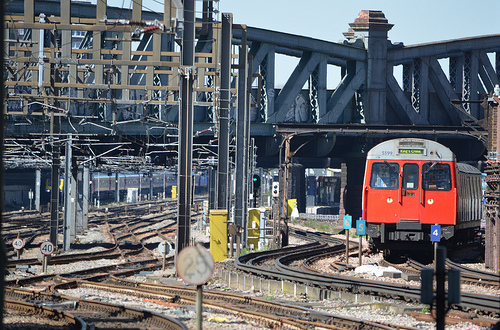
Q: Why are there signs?
A: To indicate tracks.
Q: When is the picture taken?
A: During the day.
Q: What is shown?
A: A train.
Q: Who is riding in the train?
A: Passengers.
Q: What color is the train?
A: Red.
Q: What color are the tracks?
A: Grey.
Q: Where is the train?
A: Leaving the scene.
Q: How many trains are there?
A: One.